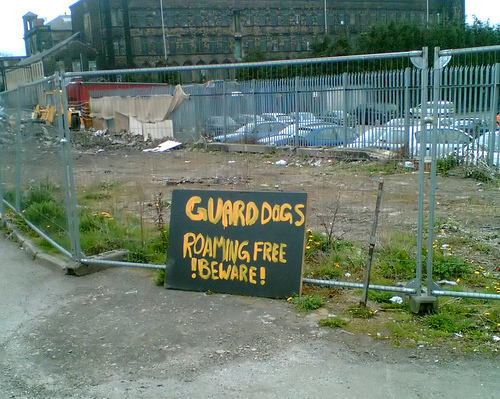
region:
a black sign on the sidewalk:
[158, 185, 315, 300]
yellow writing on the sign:
[178, 194, 304, 287]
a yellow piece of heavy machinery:
[31, 86, 85, 136]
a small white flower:
[341, 266, 354, 283]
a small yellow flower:
[302, 241, 314, 252]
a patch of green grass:
[1, 177, 499, 354]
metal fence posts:
[411, 42, 446, 302]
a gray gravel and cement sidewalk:
[2, 233, 498, 397]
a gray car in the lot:
[382, 120, 481, 160]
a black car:
[284, 118, 367, 157]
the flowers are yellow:
[441, 249, 496, 282]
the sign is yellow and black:
[173, 190, 321, 320]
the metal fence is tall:
[25, 65, 217, 297]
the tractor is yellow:
[38, 79, 80, 152]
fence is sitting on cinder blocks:
[39, 241, 152, 303]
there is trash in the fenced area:
[79, 125, 203, 157]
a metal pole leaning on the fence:
[348, 157, 376, 350]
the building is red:
[73, 77, 132, 114]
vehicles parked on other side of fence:
[221, 112, 496, 172]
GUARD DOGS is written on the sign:
[196, 183, 326, 232]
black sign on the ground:
[164, 190, 306, 295]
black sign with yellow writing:
[161, 192, 306, 293]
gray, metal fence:
[1, 43, 498, 298]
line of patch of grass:
[0, 180, 497, 349]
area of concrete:
[0, 228, 499, 398]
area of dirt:
[9, 149, 498, 259]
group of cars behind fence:
[206, 98, 498, 161]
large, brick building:
[69, 0, 461, 70]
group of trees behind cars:
[243, 13, 498, 107]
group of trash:
[15, 79, 189, 144]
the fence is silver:
[67, 39, 482, 243]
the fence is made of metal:
[37, 56, 467, 266]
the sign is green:
[129, 179, 316, 303]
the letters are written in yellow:
[132, 156, 313, 307]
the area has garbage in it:
[2, 60, 212, 172]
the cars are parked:
[215, 85, 473, 166]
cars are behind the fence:
[202, 75, 482, 170]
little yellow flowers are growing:
[3, 179, 115, 237]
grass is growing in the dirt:
[344, 240, 489, 344]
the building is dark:
[67, 0, 471, 45]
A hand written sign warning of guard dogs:
[167, 184, 312, 305]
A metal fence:
[6, 50, 498, 322]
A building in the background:
[19, 1, 476, 71]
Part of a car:
[375, 123, 470, 165]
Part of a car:
[259, 117, 344, 149]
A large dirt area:
[0, 124, 497, 266]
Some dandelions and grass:
[300, 222, 364, 315]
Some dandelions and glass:
[89, 198, 125, 238]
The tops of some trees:
[234, 15, 499, 83]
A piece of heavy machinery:
[30, 80, 93, 148]